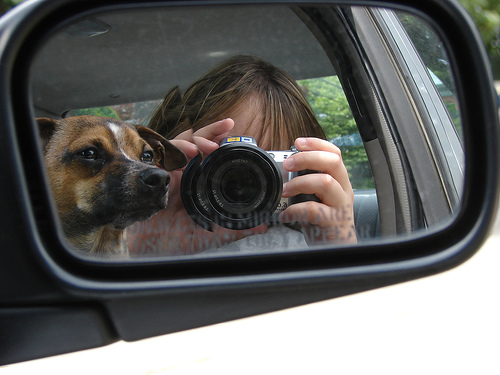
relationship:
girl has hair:
[140, 52, 359, 259] [146, 58, 327, 150]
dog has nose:
[34, 115, 188, 258] [140, 166, 171, 188]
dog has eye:
[34, 115, 188, 258] [141, 149, 154, 162]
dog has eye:
[34, 115, 188, 258] [78, 148, 101, 160]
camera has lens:
[180, 136, 322, 233] [181, 142, 283, 234]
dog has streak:
[34, 115, 188, 258] [105, 121, 136, 162]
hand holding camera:
[157, 117, 268, 256] [180, 136, 322, 233]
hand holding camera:
[278, 136, 357, 247] [180, 136, 322, 233]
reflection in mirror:
[32, 3, 466, 262] [1, 0, 499, 367]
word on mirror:
[295, 224, 373, 244] [1, 0, 499, 367]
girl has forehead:
[140, 52, 359, 259] [202, 91, 297, 150]